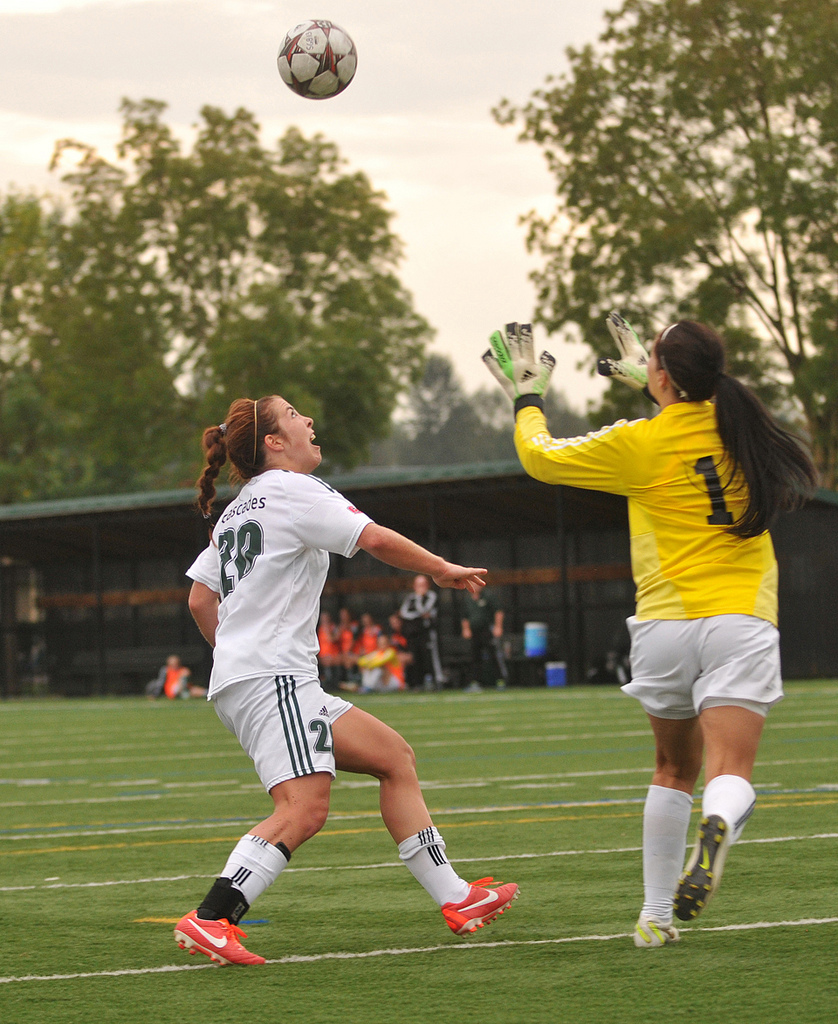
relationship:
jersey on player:
[509, 394, 778, 653] [509, 274, 815, 731]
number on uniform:
[213, 519, 263, 608] [177, 467, 387, 780]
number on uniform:
[693, 455, 736, 526] [513, 396, 791, 728]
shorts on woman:
[211, 676, 362, 788] [175, 394, 521, 965]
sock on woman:
[630, 785, 691, 946] [175, 394, 521, 965]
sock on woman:
[631, 777, 704, 932] [175, 394, 521, 965]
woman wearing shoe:
[175, 394, 521, 965] [436, 873, 527, 936]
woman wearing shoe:
[175, 394, 521, 965] [177, 908, 272, 973]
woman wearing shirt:
[175, 394, 521, 965] [509, 399, 795, 627]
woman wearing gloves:
[175, 394, 521, 965] [480, 315, 563, 406]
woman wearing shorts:
[175, 394, 521, 965] [211, 676, 362, 788]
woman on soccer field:
[175, 394, 521, 965] [0, 685, 838, 1021]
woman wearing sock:
[175, 394, 521, 965] [692, 775, 759, 826]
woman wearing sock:
[175, 394, 521, 965] [635, 784, 694, 925]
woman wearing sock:
[175, 394, 521, 965] [393, 825, 472, 908]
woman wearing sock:
[175, 394, 521, 965] [209, 827, 286, 909]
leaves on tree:
[491, 0, 836, 495] [486, 4, 836, 485]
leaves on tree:
[0, 95, 434, 518] [0, 97, 446, 503]